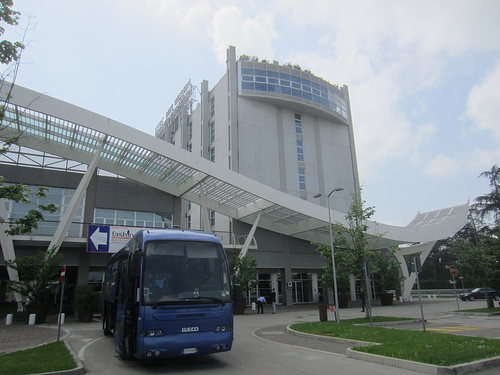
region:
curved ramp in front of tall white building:
[2, 47, 477, 306]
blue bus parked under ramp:
[97, 137, 240, 361]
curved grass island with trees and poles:
[285, 182, 495, 368]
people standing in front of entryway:
[240, 265, 280, 313]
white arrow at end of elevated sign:
[84, 217, 146, 253]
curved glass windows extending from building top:
[229, 56, 355, 123]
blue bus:
[118, 219, 240, 359]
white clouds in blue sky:
[339, 9, 396, 50]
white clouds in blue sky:
[380, 148, 410, 179]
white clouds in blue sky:
[445, 63, 471, 85]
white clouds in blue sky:
[45, 18, 80, 48]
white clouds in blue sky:
[103, 69, 133, 94]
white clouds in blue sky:
[146, 8, 188, 43]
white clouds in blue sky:
[271, 3, 337, 34]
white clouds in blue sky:
[379, 19, 434, 74]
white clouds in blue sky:
[394, 109, 439, 151]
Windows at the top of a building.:
[238, 65, 355, 118]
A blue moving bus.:
[96, 218, 247, 373]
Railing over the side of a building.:
[11, 84, 476, 243]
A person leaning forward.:
[256, 293, 268, 312]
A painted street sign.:
[416, 320, 483, 339]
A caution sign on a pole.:
[52, 260, 72, 347]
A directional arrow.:
[86, 219, 114, 256]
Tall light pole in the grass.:
[311, 183, 352, 329]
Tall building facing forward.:
[146, 43, 386, 305]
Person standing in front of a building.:
[266, 285, 287, 317]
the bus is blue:
[90, 225, 243, 374]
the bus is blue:
[101, 223, 248, 369]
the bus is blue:
[91, 220, 266, 373]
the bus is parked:
[81, 225, 260, 370]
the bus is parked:
[92, 228, 227, 371]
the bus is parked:
[102, 223, 263, 360]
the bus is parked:
[97, 219, 254, 368]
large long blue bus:
[96, 230, 235, 366]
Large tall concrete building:
[156, 44, 365, 312]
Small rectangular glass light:
[143, 329, 161, 341]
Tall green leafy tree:
[311, 189, 397, 314]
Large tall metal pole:
[311, 186, 351, 326]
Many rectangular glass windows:
[291, 111, 310, 192]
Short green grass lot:
[289, 314, 498, 374]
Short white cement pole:
[28, 309, 38, 324]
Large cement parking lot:
[62, 305, 499, 372]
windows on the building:
[278, 120, 315, 190]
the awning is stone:
[31, 140, 456, 257]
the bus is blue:
[130, 232, 247, 364]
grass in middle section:
[355, 340, 473, 370]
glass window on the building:
[238, 80, 254, 89]